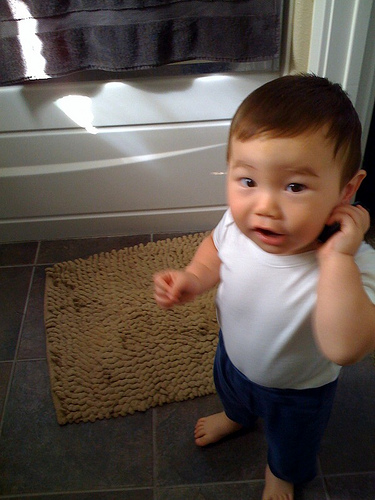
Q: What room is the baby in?
A: Bathroom.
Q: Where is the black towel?
A: Hanging over the side of the bathtub.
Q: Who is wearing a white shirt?
A: The baby.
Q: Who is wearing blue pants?
A: The baby.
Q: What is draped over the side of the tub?
A: Black towel.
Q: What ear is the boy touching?
A: Left ear.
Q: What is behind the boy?
A: A bathtub.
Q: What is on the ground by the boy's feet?
A: A bathroom mat.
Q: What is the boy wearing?
A: A shirt and pants.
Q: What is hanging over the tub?
A: A towel.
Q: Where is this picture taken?
A: In a bathroom.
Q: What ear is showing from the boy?
A: The boy's left.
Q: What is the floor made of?
A: Tiles.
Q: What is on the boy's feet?
A: Nothing.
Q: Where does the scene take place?
A: In a bathroom.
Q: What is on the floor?
A: A mat.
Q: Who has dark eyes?
A: Little boy.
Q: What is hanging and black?
A: Towel.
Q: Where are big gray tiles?
A: On the floor.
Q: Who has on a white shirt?
A: The boy.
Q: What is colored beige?
A: A mat.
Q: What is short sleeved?
A: White shirt.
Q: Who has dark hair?
A: The little boy.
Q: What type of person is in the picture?
A: A child.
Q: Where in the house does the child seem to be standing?
A: The bathroom.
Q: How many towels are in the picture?
A: One.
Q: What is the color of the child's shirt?
A: White.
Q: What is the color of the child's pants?
A: Blue.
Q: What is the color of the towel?
A: Grey.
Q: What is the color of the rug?
A: Brown.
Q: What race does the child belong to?
A: Asian.